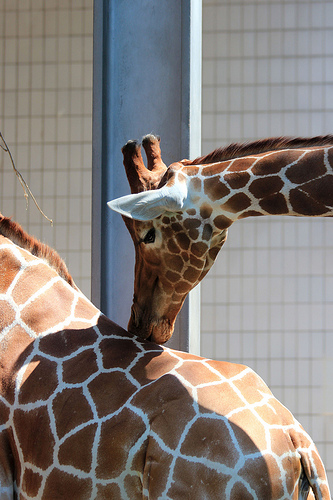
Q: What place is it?
A: It is a zoo.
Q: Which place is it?
A: It is a zoo.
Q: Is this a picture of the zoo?
A: Yes, it is showing the zoo.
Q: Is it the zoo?
A: Yes, it is the zoo.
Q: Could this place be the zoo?
A: Yes, it is the zoo.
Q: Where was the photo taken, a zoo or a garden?
A: It was taken at a zoo.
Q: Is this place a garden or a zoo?
A: It is a zoo.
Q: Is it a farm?
A: No, it is a zoo.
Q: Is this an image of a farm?
A: No, the picture is showing a zoo.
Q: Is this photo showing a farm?
A: No, the picture is showing a zoo.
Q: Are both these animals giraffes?
A: Yes, all the animals are giraffes.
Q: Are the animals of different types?
A: No, all the animals are giraffes.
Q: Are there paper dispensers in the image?
A: No, there are no paper dispensers.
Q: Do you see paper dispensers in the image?
A: No, there are no paper dispensers.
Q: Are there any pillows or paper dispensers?
A: No, there are no paper dispensers or pillows.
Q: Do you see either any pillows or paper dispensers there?
A: No, there are no paper dispensers or pillows.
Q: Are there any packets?
A: No, there are no packets.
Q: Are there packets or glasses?
A: No, there are no packets or glasses.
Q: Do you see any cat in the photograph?
A: No, there are no cats.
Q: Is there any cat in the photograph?
A: No, there are no cats.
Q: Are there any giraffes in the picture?
A: Yes, there is a giraffe.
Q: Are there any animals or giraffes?
A: Yes, there is a giraffe.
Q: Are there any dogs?
A: No, there are no dogs.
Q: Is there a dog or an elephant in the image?
A: No, there are no dogs or elephants.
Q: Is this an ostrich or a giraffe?
A: This is a giraffe.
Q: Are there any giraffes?
A: Yes, there is a giraffe.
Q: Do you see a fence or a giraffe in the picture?
A: Yes, there is a giraffe.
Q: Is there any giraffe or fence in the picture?
A: Yes, there is a giraffe.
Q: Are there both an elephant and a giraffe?
A: No, there is a giraffe but no elephants.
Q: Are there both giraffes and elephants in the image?
A: No, there is a giraffe but no elephants.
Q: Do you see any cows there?
A: No, there are no cows.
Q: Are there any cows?
A: No, there are no cows.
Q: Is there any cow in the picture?
A: No, there are no cows.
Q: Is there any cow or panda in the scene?
A: No, there are no cows or pandas.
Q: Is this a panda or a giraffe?
A: This is a giraffe.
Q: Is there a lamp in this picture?
A: No, there are no lamps.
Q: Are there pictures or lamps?
A: No, there are no lamps or pictures.